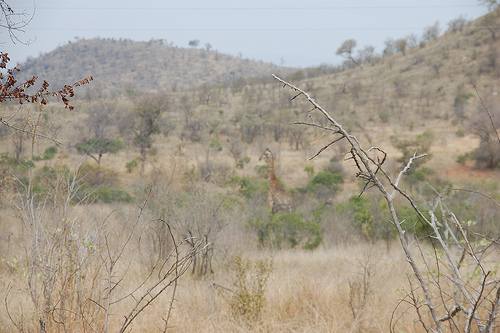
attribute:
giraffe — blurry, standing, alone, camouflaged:
[260, 151, 297, 213]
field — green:
[2, 95, 499, 332]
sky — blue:
[1, 1, 499, 71]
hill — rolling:
[2, 39, 327, 98]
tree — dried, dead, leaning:
[274, 74, 499, 332]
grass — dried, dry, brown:
[3, 101, 498, 332]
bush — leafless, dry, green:
[2, 166, 215, 333]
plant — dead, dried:
[273, 72, 498, 332]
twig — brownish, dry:
[273, 76, 498, 330]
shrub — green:
[306, 164, 345, 202]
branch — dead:
[273, 76, 445, 333]